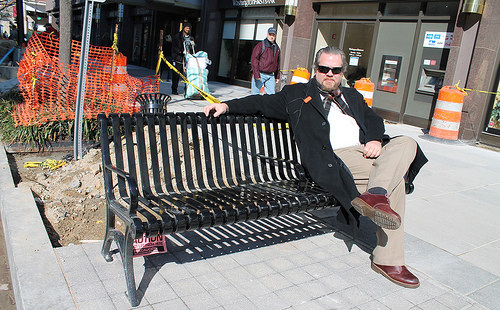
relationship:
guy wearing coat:
[203, 45, 427, 288] [230, 79, 373, 232]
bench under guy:
[99, 106, 364, 298] [203, 45, 427, 288]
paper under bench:
[135, 229, 168, 258] [99, 106, 364, 298]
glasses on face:
[312, 62, 343, 74] [313, 53, 346, 92]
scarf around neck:
[309, 89, 353, 118] [315, 84, 347, 100]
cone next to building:
[430, 86, 465, 140] [10, 0, 499, 162]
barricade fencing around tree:
[9, 31, 161, 126] [52, 1, 81, 116]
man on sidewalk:
[248, 25, 283, 97] [124, 62, 495, 279]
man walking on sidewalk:
[248, 25, 283, 97] [124, 62, 495, 279]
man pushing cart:
[170, 20, 195, 94] [184, 40, 213, 105]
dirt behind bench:
[40, 120, 246, 245] [99, 106, 364, 298]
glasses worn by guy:
[317, 66, 343, 75] [201, 43, 428, 291]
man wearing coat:
[248, 25, 283, 97] [251, 39, 282, 79]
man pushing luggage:
[170, 20, 195, 94] [183, 37, 212, 105]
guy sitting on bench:
[203, 45, 427, 288] [99, 106, 364, 298]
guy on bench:
[203, 45, 427, 288] [99, 106, 364, 298]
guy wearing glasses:
[203, 45, 427, 288] [317, 66, 343, 75]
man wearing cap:
[248, 25, 283, 97] [270, 28, 279, 35]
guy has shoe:
[203, 45, 427, 288] [375, 258, 420, 290]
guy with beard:
[203, 45, 427, 288] [312, 72, 344, 93]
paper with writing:
[135, 229, 168, 258] [138, 237, 165, 251]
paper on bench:
[135, 229, 168, 258] [96, 111, 363, 307]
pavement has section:
[0, 63, 495, 303] [13, 108, 271, 246]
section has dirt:
[13, 108, 271, 246] [40, 120, 246, 239]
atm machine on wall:
[416, 63, 441, 91] [278, 5, 499, 150]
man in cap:
[248, 25, 283, 97] [270, 28, 279, 35]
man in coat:
[248, 25, 283, 97] [252, 44, 284, 79]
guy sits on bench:
[203, 45, 427, 288] [96, 111, 363, 307]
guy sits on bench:
[203, 45, 427, 288] [99, 106, 364, 298]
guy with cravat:
[203, 45, 427, 288] [317, 84, 355, 126]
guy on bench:
[203, 45, 427, 288] [96, 111, 363, 307]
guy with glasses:
[203, 45, 427, 288] [317, 66, 343, 75]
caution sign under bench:
[131, 209, 169, 262] [99, 106, 364, 298]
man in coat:
[248, 25, 283, 97] [251, 39, 282, 79]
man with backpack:
[248, 25, 283, 97] [260, 44, 279, 67]